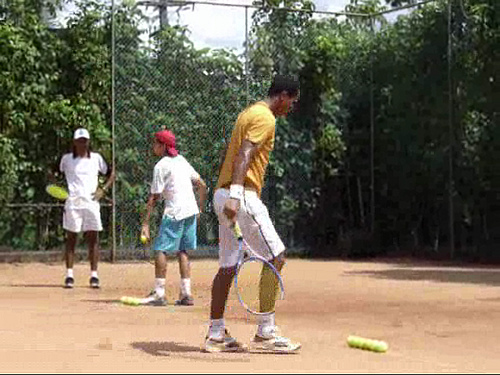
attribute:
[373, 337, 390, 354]
ball — yellow, small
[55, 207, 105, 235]
shorts — white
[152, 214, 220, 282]
shorts — blue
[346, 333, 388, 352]
tennis ball — yellow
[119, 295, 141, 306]
tennis ball — yellow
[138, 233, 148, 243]
tennis ball — yellow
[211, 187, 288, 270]
shorts — white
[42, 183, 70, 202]
tennis racket — yellow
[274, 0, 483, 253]
fence — tall, chain, link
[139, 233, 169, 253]
tennis ball — yellow, small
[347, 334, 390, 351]
balls — yellow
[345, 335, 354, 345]
ball — small, yellow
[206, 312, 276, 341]
socks — white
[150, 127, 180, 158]
cap — red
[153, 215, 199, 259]
shorts — blue